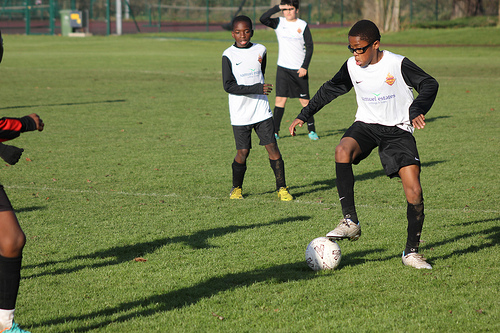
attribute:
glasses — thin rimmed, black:
[347, 40, 382, 57]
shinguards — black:
[402, 199, 426, 256]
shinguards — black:
[333, 158, 358, 223]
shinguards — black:
[265, 152, 287, 190]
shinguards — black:
[230, 157, 248, 189]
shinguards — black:
[270, 102, 285, 132]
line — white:
[4, 183, 499, 214]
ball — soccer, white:
[303, 231, 343, 273]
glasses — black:
[346, 44, 371, 54]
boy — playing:
[288, 19, 440, 269]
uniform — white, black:
[220, 42, 276, 147]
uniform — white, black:
[296, 50, 440, 177]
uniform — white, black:
[258, 2, 312, 97]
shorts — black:
[335, 116, 425, 178]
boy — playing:
[222, 17, 291, 202]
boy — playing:
[260, 2, 317, 145]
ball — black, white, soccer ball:
[303, 233, 341, 271]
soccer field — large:
[56, 102, 215, 248]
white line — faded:
[0, 170, 498, 216]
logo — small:
[378, 71, 412, 92]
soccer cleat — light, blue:
[306, 127, 323, 142]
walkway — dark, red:
[1, 17, 361, 37]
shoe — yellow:
[273, 186, 294, 202]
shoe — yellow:
[225, 186, 245, 201]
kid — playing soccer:
[258, 1, 320, 141]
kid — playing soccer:
[218, 14, 295, 201]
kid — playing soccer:
[286, 18, 437, 270]